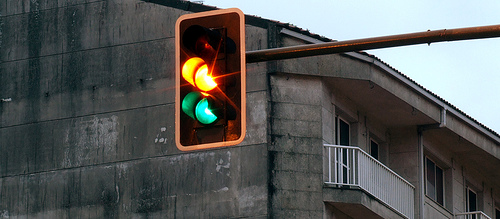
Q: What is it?
A: Light.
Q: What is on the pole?
A: Lights.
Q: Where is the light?
A: On the pole.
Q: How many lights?
A: 1.